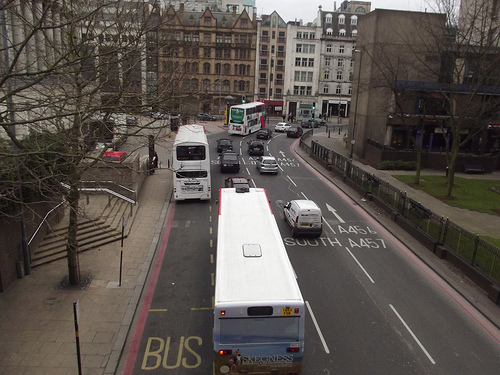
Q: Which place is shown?
A: It is a street.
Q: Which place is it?
A: It is a street.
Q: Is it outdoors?
A: Yes, it is outdoors.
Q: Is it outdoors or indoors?
A: It is outdoors.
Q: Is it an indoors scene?
A: No, it is outdoors.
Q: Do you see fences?
A: Yes, there is a fence.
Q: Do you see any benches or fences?
A: Yes, there is a fence.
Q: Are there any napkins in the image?
A: No, there are no napkins.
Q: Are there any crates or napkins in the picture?
A: No, there are no napkins or crates.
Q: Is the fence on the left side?
A: No, the fence is on the right of the image.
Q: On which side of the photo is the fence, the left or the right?
A: The fence is on the right of the image.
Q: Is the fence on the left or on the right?
A: The fence is on the right of the image.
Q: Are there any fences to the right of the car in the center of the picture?
A: Yes, there is a fence to the right of the car.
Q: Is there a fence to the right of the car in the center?
A: Yes, there is a fence to the right of the car.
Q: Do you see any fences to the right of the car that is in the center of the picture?
A: Yes, there is a fence to the right of the car.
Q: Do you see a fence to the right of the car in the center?
A: Yes, there is a fence to the right of the car.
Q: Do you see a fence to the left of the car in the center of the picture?
A: No, the fence is to the right of the car.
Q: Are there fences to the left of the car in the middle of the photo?
A: No, the fence is to the right of the car.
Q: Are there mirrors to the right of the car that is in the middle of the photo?
A: No, there is a fence to the right of the car.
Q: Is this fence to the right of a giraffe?
A: No, the fence is to the right of a car.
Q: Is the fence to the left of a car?
A: No, the fence is to the right of a car.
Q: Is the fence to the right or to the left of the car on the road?
A: The fence is to the right of the car.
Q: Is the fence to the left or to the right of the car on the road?
A: The fence is to the right of the car.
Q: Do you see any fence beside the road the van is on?
A: Yes, there is a fence beside the road.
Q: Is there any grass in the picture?
A: Yes, there is grass.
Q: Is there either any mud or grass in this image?
A: Yes, there is grass.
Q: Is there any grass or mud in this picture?
A: Yes, there is grass.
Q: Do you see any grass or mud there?
A: Yes, there is grass.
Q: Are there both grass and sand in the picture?
A: No, there is grass but no sand.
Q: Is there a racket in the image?
A: No, there are no rackets.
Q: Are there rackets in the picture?
A: No, there are no rackets.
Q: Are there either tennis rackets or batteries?
A: No, there are no tennis rackets or batteries.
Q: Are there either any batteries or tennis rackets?
A: No, there are no tennis rackets or batteries.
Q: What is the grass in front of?
A: The grass is in front of the building.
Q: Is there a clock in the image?
A: No, there are no clocks.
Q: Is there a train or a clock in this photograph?
A: No, there are no clocks or trains.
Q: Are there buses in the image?
A: Yes, there is a bus.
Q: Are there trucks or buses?
A: Yes, there is a bus.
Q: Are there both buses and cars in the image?
A: Yes, there are both a bus and a car.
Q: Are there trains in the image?
A: No, there are no trains.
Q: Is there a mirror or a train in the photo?
A: No, there are no trains or mirrors.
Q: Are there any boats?
A: No, there are no boats.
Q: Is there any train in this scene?
A: No, there are no trains.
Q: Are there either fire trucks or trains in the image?
A: No, there are no trains or fire trucks.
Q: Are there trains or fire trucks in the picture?
A: No, there are no trains or fire trucks.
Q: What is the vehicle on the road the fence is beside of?
A: The vehicle is a car.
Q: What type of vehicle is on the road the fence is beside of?
A: The vehicle is a car.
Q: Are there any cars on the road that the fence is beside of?
A: Yes, there is a car on the road.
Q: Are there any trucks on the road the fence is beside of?
A: No, there is a car on the road.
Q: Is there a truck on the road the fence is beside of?
A: No, there is a car on the road.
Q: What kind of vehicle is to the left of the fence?
A: The vehicle is a car.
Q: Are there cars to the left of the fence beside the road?
A: Yes, there is a car to the left of the fence.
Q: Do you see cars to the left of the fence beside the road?
A: Yes, there is a car to the left of the fence.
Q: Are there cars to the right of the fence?
A: No, the car is to the left of the fence.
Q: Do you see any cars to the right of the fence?
A: No, the car is to the left of the fence.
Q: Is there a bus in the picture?
A: Yes, there is a bus.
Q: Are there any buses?
A: Yes, there is a bus.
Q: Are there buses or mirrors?
A: Yes, there is a bus.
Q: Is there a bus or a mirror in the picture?
A: Yes, there is a bus.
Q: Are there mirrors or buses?
A: Yes, there is a bus.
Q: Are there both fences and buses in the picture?
A: Yes, there are both a bus and a fence.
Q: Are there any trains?
A: No, there are no trains.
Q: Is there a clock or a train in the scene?
A: No, there are no trains or clocks.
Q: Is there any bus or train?
A: Yes, there is a bus.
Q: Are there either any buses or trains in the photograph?
A: Yes, there is a bus.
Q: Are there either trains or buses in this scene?
A: Yes, there is a bus.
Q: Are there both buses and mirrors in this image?
A: No, there is a bus but no mirrors.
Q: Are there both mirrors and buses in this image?
A: No, there is a bus but no mirrors.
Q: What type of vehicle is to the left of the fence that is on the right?
A: The vehicle is a bus.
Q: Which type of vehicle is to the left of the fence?
A: The vehicle is a bus.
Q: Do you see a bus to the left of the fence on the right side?
A: Yes, there is a bus to the left of the fence.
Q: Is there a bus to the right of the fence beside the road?
A: No, the bus is to the left of the fence.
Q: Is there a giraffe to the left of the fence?
A: No, there is a bus to the left of the fence.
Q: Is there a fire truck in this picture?
A: No, there are no fire trucks.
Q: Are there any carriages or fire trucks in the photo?
A: No, there are no fire trucks or carriages.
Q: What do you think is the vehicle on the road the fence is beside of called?
A: The vehicle is a van.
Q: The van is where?
A: The van is on the road.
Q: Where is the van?
A: The van is on the road.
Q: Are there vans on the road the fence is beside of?
A: Yes, there is a van on the road.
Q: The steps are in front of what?
A: The steps are in front of the building.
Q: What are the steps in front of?
A: The steps are in front of the building.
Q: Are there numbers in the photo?
A: Yes, there are numbers.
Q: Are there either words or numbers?
A: Yes, there are numbers.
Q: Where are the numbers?
A: The numbers are on the road.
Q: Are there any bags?
A: No, there are no bags.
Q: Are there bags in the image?
A: No, there are no bags.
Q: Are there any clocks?
A: No, there are no clocks.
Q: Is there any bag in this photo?
A: No, there are no bags.